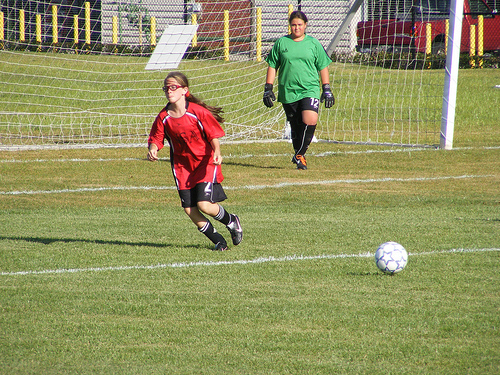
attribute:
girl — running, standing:
[159, 81, 186, 93]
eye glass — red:
[162, 83, 182, 93]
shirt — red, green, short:
[139, 105, 233, 184]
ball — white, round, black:
[372, 238, 408, 276]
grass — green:
[0, 0, 499, 48]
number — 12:
[309, 97, 321, 111]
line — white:
[7, 243, 499, 271]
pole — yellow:
[0, 4, 484, 70]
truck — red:
[354, 3, 499, 70]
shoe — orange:
[282, 143, 310, 172]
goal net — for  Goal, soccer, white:
[3, 1, 463, 159]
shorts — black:
[171, 181, 225, 207]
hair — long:
[163, 72, 223, 119]